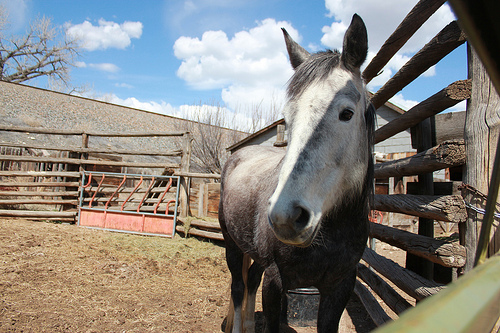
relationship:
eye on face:
[336, 102, 355, 128] [269, 53, 368, 250]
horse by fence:
[202, 14, 383, 332] [324, 4, 500, 331]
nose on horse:
[264, 175, 332, 252] [202, 14, 383, 332]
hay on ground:
[74, 252, 146, 291] [5, 230, 227, 332]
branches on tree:
[36, 71, 68, 83] [3, 20, 71, 88]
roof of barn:
[1, 77, 261, 173] [1, 74, 250, 241]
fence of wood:
[324, 4, 500, 331] [470, 117, 498, 176]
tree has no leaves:
[3, 20, 71, 88] [55, 66, 68, 81]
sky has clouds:
[82, 2, 275, 96] [67, 19, 141, 55]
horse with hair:
[202, 14, 383, 332] [292, 53, 341, 99]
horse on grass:
[202, 14, 383, 332] [1, 213, 347, 332]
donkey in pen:
[202, 14, 383, 332] [3, 7, 499, 327]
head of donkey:
[269, 53, 368, 250] [202, 14, 383, 332]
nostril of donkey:
[291, 202, 314, 225] [202, 14, 383, 332]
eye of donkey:
[336, 102, 355, 128] [202, 14, 383, 332]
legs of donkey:
[227, 250, 356, 331] [202, 14, 383, 332]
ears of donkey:
[273, 15, 376, 72] [202, 14, 383, 332]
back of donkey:
[232, 144, 287, 166] [202, 14, 383, 332]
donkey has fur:
[202, 14, 383, 332] [239, 156, 258, 199]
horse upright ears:
[202, 14, 383, 332] [273, 15, 376, 72]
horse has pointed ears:
[202, 14, 383, 332] [273, 15, 376, 72]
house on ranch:
[219, 83, 425, 218] [3, 7, 499, 327]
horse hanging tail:
[202, 14, 383, 332] [219, 188, 236, 290]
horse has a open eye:
[202, 14, 383, 332] [336, 102, 355, 128]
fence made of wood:
[324, 4, 500, 331] [470, 117, 498, 176]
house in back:
[219, 83, 425, 218] [373, 74, 467, 206]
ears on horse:
[273, 15, 376, 72] [202, 14, 383, 332]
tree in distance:
[3, 20, 71, 88] [4, 27, 479, 120]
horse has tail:
[202, 14, 383, 332] [219, 188, 236, 290]